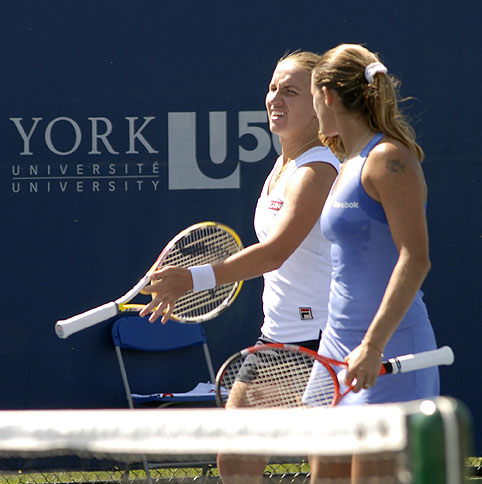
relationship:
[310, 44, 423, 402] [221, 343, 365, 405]
woman holding tennis racket